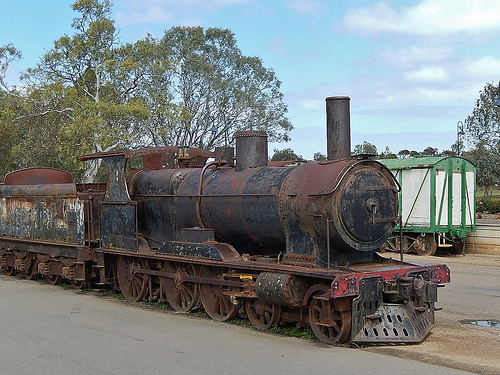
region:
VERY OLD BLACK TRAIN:
[3, 85, 416, 355]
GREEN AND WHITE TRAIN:
[370, 128, 479, 260]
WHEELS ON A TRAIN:
[105, 248, 364, 340]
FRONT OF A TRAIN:
[323, 263, 456, 338]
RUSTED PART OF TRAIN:
[9, 165, 131, 295]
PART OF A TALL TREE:
[63, 45, 144, 175]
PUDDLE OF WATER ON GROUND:
[457, 305, 497, 337]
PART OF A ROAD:
[77, 310, 126, 360]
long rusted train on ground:
[1, 83, 458, 354]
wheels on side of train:
[105, 258, 361, 341]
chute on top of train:
[314, 90, 364, 160]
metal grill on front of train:
[344, 270, 450, 351]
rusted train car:
[2, 171, 103, 260]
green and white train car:
[380, 148, 485, 258]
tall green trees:
[1, 1, 293, 166]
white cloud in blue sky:
[335, 1, 498, 58]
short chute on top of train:
[220, 125, 277, 173]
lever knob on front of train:
[360, 195, 387, 230]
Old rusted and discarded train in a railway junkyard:
[0, 96, 450, 342]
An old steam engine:
[77, 97, 449, 342]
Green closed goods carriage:
[377, 156, 476, 253]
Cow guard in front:
[350, 275, 434, 342]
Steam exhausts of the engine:
[234, 97, 349, 169]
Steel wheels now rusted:
[116, 255, 349, 345]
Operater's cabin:
[78, 151, 134, 252]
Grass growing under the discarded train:
[52, 280, 357, 349]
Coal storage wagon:
[0, 168, 102, 253]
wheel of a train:
[301, 285, 342, 345]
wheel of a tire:
[240, 275, 287, 321]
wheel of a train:
[155, 255, 200, 305]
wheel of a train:
[30, 251, 60, 282]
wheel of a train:
[11, 245, 31, 281]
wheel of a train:
[1, 245, 13, 270]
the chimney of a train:
[322, 85, 358, 158]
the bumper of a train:
[350, 280, 442, 339]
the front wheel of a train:
[307, 302, 348, 349]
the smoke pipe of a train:
[235, 120, 272, 166]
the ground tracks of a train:
[382, 319, 493, 374]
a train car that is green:
[411, 146, 485, 250]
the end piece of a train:
[440, 221, 476, 243]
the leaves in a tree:
[159, 28, 214, 63]